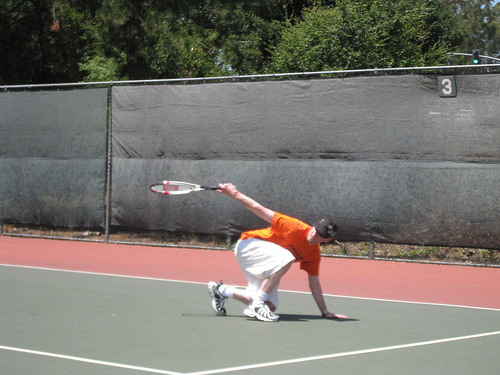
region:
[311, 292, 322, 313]
part of an arm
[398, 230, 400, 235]
edge of a court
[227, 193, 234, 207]
part of a racket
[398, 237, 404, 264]
part of a grass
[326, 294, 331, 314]
part of a shirt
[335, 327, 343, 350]
part of an arm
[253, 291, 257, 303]
part of a sock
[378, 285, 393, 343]
edge of a court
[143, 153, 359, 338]
man playing at a tennis court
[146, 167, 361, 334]
man playing a game of tennis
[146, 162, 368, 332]
man with a three point pose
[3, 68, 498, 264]
black fencing around the court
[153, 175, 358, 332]
man holding a tennis racket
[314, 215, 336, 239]
black hat of the tennis player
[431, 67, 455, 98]
number three against the fence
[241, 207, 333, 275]
orange shirt of the tennis player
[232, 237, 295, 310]
white shorts of the tennis player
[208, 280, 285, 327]
tennis shoes of the tennis player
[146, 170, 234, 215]
tennis racquet in a horizontal position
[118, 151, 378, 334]
tennis player with a desperate return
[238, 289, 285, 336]
mens' tennis shoes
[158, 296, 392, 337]
shadow of tennis player on a hardcourt surface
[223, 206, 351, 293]
orange tennis shirt on a male human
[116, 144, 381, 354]
man playing tennis on a hardcourt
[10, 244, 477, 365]
artificial surface of a tennis court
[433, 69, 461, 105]
the number three in white paint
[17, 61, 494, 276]
fence with privacy protector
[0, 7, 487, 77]
row of green trees outside a tennis court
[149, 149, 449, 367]
a man on the tennis court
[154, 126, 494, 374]
a man on the court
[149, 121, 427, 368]
a man kneeling on the tennis court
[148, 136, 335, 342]
a man holding a racket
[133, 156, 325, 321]
a man hodling a tennis racket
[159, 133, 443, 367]
a man wearing a shirt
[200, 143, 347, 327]
a man wearing an orange shirt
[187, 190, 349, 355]
a man wearing a hat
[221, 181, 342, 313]
a man wearing shorts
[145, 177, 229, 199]
red, white and black tennis racket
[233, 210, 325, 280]
orange shirt on the player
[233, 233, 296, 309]
white shorts on the player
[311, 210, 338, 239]
black hat on the player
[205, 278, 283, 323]
white and black shoes on the player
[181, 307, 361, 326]
shadow on the ground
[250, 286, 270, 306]
white sock on the player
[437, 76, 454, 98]
white number on the fence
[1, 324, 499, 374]
white lines on the court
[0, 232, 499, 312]
red section of the court